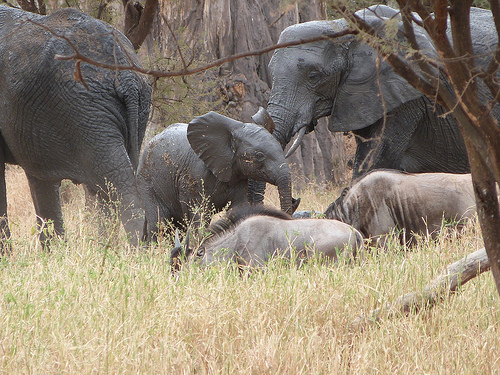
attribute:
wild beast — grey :
[325, 157, 497, 247]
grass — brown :
[5, 256, 497, 371]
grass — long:
[79, 197, 216, 304]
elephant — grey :
[1, 0, 178, 251]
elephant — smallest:
[138, 115, 311, 222]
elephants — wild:
[2, 3, 499, 270]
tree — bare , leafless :
[269, 2, 489, 373]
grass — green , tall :
[118, 261, 378, 367]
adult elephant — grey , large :
[245, 3, 498, 201]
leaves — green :
[383, 19, 400, 49]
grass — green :
[0, 130, 498, 373]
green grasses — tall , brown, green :
[54, 268, 282, 366]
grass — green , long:
[4, 163, 494, 373]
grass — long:
[2, 245, 499, 374]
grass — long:
[221, 280, 321, 338]